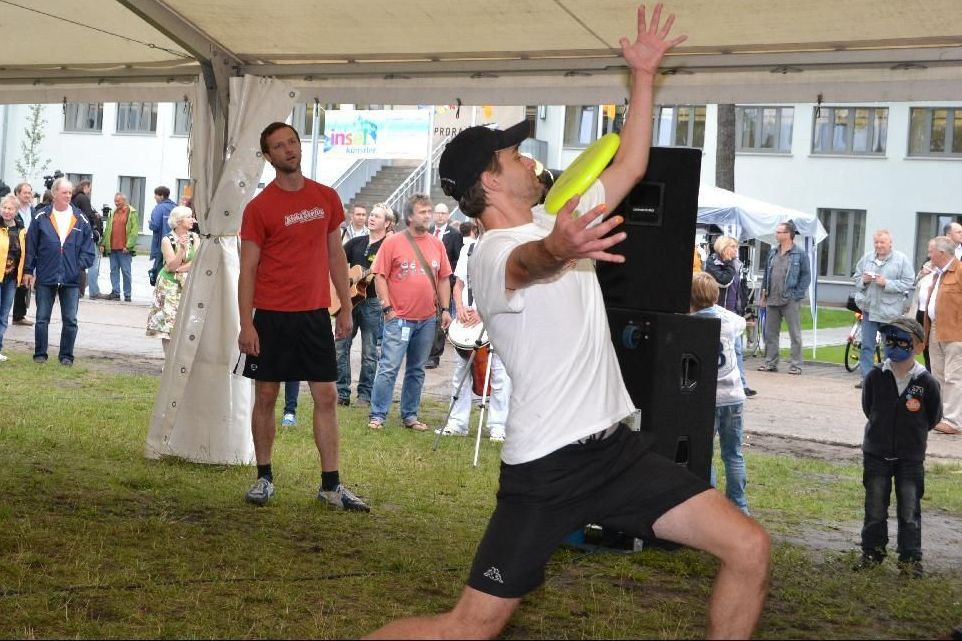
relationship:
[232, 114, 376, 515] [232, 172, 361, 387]
man wearing clothing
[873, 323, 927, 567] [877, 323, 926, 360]
boy with face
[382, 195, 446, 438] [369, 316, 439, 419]
man in jeans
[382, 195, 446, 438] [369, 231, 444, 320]
man in shirt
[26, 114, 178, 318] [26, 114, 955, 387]
wall in building